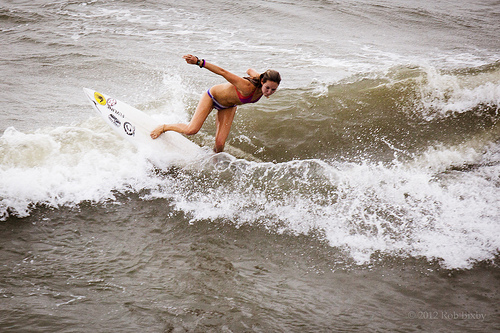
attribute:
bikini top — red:
[225, 77, 259, 124]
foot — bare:
[148, 108, 184, 148]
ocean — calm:
[12, 17, 333, 93]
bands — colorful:
[165, 36, 210, 84]